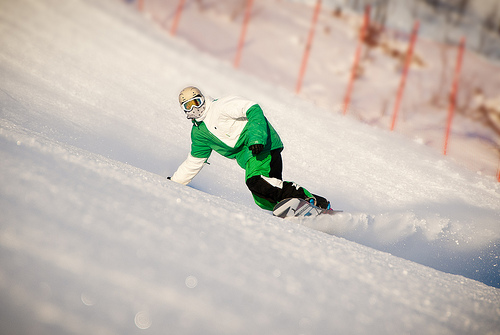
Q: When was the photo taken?
A: Daytime.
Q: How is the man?
A: In motion.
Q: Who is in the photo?
A: A person.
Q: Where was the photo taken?
A: On a hill.